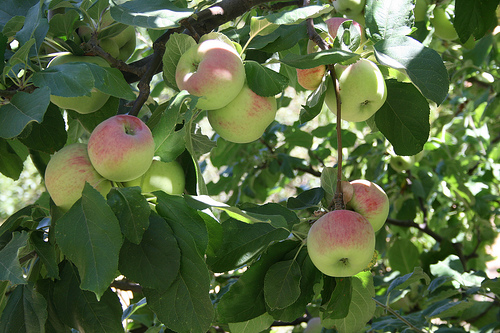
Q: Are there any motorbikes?
A: No, there are no motorbikes.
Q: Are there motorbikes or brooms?
A: No, there are no motorbikes or brooms.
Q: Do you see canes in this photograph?
A: No, there are no canes.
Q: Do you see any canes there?
A: No, there are no canes.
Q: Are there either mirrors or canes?
A: No, there are no canes or mirrors.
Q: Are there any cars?
A: No, there are no cars.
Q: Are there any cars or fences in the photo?
A: No, there are no cars or fences.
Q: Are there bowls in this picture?
A: No, there are no bowls.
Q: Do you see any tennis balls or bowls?
A: No, there are no bowls or tennis balls.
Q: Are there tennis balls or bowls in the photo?
A: No, there are no bowls or tennis balls.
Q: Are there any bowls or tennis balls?
A: No, there are no bowls or tennis balls.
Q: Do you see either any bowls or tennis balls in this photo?
A: No, there are no bowls or tennis balls.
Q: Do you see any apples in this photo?
A: Yes, there are apples.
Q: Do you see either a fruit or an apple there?
A: Yes, there are apples.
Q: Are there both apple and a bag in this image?
A: No, there are apples but no bags.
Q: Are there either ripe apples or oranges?
A: Yes, there are ripe apples.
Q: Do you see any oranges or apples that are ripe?
A: Yes, the apples are ripe.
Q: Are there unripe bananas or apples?
A: Yes, there are unripe apples.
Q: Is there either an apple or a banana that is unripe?
A: Yes, the apples are unripe.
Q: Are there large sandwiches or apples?
A: Yes, there are large apples.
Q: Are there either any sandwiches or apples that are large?
A: Yes, the apples are large.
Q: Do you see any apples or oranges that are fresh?
A: Yes, the apples are fresh.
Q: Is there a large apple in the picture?
A: Yes, there are large apples.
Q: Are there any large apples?
A: Yes, there are large apples.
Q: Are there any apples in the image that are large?
A: Yes, there are apples that are large.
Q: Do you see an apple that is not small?
A: Yes, there are large apples.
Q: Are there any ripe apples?
A: Yes, there are ripe apples.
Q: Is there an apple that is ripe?
A: Yes, there are apples that are ripe.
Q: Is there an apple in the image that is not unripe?
A: Yes, there are ripe apples.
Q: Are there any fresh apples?
A: Yes, there are fresh apples.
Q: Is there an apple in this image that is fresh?
A: Yes, there are apples that are fresh.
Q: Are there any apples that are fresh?
A: Yes, there are apples that are fresh.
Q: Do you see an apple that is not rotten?
A: Yes, there are fresh apples.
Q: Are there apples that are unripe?
A: Yes, there are unripe apples.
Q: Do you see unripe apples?
A: Yes, there are unripe apples.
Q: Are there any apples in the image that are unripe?
A: Yes, there are apples that are unripe.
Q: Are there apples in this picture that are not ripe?
A: Yes, there are unripe apples.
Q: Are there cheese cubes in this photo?
A: No, there are no cheese cubes.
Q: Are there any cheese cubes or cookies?
A: No, there are no cheese cubes or cookies.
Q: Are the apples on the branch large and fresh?
A: Yes, the apples are large and fresh.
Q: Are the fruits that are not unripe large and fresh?
A: Yes, the apples are large and fresh.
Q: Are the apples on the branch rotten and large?
A: No, the apples are large but fresh.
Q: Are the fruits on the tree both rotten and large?
A: No, the apples are large but fresh.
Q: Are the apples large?
A: Yes, the apples are large.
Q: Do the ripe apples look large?
A: Yes, the apples are large.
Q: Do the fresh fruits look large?
A: Yes, the apples are large.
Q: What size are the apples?
A: The apples are large.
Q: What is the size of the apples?
A: The apples are large.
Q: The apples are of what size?
A: The apples are large.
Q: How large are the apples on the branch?
A: The apples are large.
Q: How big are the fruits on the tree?
A: The apples are large.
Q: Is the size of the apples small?
A: No, the apples are large.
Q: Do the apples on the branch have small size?
A: No, the apples are large.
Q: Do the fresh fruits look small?
A: No, the apples are large.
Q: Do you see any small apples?
A: No, there are apples but they are large.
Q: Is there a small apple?
A: No, there are apples but they are large.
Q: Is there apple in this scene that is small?
A: No, there are apples but they are large.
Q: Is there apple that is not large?
A: No, there are apples but they are large.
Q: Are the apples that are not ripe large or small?
A: The apples are large.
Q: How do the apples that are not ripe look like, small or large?
A: The apples are large.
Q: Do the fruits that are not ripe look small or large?
A: The apples are large.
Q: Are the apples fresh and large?
A: Yes, the apples are fresh and large.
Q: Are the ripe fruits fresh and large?
A: Yes, the apples are fresh and large.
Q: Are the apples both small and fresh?
A: No, the apples are fresh but large.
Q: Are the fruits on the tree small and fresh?
A: No, the apples are fresh but large.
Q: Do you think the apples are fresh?
A: Yes, the apples are fresh.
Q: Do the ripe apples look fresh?
A: Yes, the apples are fresh.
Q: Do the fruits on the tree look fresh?
A: Yes, the apples are fresh.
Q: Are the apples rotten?
A: No, the apples are fresh.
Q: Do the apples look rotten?
A: No, the apples are fresh.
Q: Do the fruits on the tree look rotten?
A: No, the apples are fresh.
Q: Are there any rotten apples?
A: No, there are apples but they are fresh.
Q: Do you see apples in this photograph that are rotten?
A: No, there are apples but they are fresh.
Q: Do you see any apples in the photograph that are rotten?
A: No, there are apples but they are fresh.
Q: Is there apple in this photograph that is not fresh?
A: No, there are apples but they are fresh.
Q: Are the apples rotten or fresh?
A: The apples are fresh.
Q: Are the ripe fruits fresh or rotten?
A: The apples are fresh.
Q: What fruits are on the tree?
A: The fruits are apples.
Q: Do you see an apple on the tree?
A: Yes, there are apples on the tree.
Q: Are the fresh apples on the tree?
A: Yes, the apples are on the tree.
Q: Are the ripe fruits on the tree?
A: Yes, the apples are on the tree.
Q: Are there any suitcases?
A: No, there are no suitcases.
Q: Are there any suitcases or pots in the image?
A: No, there are no suitcases or pots.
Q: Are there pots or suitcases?
A: No, there are no suitcases or pots.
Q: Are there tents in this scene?
A: No, there are no tents.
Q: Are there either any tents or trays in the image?
A: No, there are no tents or trays.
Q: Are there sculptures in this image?
A: No, there are no sculptures.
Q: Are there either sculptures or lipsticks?
A: No, there are no sculptures or lipsticks.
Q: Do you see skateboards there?
A: No, there are no skateboards.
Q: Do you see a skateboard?
A: No, there are no skateboards.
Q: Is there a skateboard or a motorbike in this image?
A: No, there are no skateboards or motorcycles.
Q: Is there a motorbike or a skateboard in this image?
A: No, there are no skateboards or motorcycles.